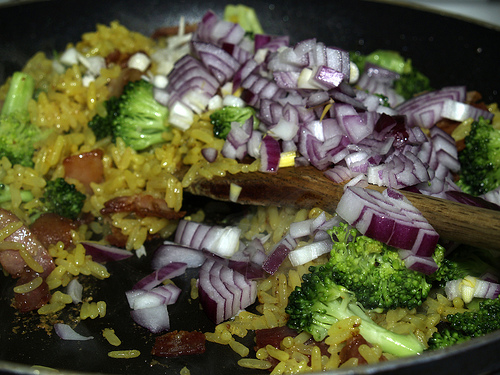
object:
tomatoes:
[34, 141, 236, 223]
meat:
[99, 193, 187, 221]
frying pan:
[0, 0, 499, 375]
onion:
[125, 284, 182, 311]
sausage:
[0, 208, 56, 281]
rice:
[45, 241, 110, 288]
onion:
[441, 97, 494, 123]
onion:
[175, 219, 241, 259]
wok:
[368, 3, 490, 83]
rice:
[164, 175, 184, 213]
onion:
[198, 258, 257, 324]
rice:
[188, 117, 215, 146]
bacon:
[151, 330, 206, 357]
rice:
[79, 20, 155, 55]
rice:
[36, 65, 123, 131]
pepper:
[62, 148, 105, 196]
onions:
[256, 136, 282, 174]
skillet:
[0, 0, 499, 375]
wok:
[7, 2, 499, 372]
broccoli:
[111, 77, 169, 150]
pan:
[0, 0, 499, 375]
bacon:
[62, 148, 105, 195]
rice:
[110, 136, 131, 173]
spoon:
[182, 163, 500, 265]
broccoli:
[349, 50, 430, 100]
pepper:
[0, 208, 56, 280]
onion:
[362, 189, 419, 251]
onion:
[165, 52, 219, 115]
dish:
[2, 5, 499, 374]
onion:
[288, 237, 332, 267]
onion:
[335, 186, 395, 244]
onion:
[334, 104, 374, 144]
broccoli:
[284, 266, 423, 357]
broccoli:
[326, 222, 433, 314]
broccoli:
[427, 296, 500, 352]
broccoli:
[458, 116, 498, 197]